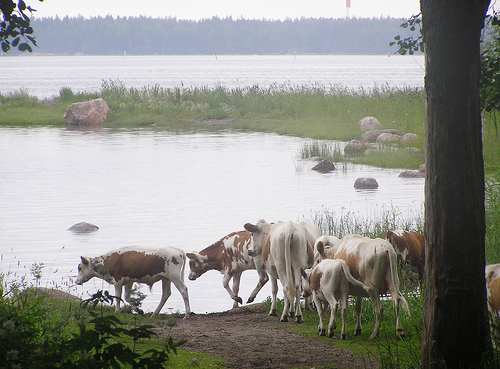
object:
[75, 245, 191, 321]
cow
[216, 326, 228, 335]
trail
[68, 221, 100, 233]
rock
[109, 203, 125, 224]
water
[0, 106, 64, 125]
grass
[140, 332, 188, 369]
plant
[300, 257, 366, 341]
cow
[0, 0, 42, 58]
tree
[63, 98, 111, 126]
rock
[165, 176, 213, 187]
water